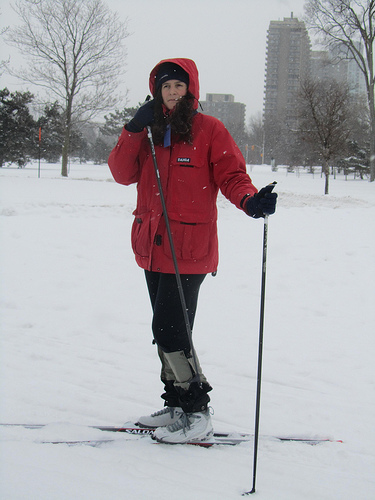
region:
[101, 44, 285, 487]
A woman outside in the snow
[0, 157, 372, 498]
White snow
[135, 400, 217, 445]
White and grey ski boots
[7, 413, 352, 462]
A pair of skis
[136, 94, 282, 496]
Black ski poles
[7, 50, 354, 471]
A woman in skis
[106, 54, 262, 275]
A red winter coat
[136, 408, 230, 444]
shoes on the feet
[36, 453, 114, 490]
snow on the ground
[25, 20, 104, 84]
branches on the tree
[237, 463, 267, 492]
ski pole in snow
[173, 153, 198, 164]
label on the coat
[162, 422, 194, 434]
laces on the shoe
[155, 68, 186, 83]
hat on the head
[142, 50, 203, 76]
hood of the coat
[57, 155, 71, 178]
trunk on the tree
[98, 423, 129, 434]
skis in the snow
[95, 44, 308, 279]
a red coat on the skier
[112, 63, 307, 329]
this lady is skiing in the city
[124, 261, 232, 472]
her legs are crossed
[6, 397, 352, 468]
her skies are covered by snow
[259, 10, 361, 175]
a building in the background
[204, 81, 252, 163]
a short building in the background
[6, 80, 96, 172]
snow covered trees in the area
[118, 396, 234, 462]
white ski boots on the lady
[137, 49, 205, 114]
she is wearing a hood on her head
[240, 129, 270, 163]
a traffic light in the background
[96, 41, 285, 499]
A lady standing on skiis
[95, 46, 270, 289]
A lady wearing a red ski jacket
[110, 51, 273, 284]
A lady wearing a red jacket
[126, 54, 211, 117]
A lady wearing a red hood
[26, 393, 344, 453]
Red, black and white skiis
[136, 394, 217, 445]
White ski shoes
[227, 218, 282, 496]
One ski rod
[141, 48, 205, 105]
A lady wearing a black knit cap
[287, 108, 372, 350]
A field with snow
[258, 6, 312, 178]
A tall building in the background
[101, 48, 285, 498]
Woman standing in the snow.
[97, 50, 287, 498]
Female skier standing in the snow.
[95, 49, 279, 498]
Woman with red coat standing in snow.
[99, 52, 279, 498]
Skier wearing gloves while standing in snow.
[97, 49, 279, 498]
Woman wearing red hooded coat.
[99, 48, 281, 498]
Woman standing with skis on.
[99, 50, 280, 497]
Female skier with black pants.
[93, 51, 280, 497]
Woman with white ski boots.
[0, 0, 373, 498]
Female skier with buildings in the background.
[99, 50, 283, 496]
Female skier wearing black cap.